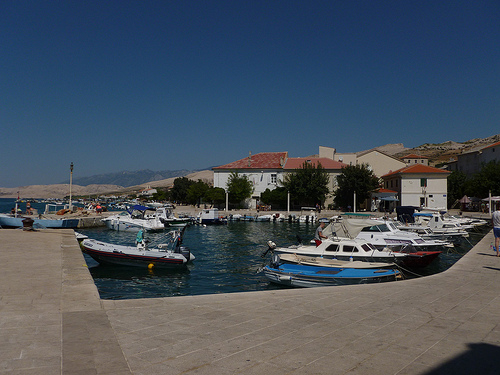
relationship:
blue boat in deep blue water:
[261, 261, 402, 288] [76, 223, 314, 300]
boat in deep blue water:
[273, 234, 413, 266] [76, 223, 314, 300]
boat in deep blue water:
[310, 218, 455, 251] [76, 223, 314, 300]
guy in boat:
[313, 221, 327, 248] [306, 213, 458, 257]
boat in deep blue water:
[306, 213, 458, 257] [76, 223, 314, 300]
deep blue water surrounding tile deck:
[76, 223, 314, 300] [6, 221, 500, 374]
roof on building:
[209, 147, 283, 173] [205, 147, 286, 205]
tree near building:
[284, 159, 329, 207] [209, 148, 346, 211]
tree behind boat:
[284, 159, 329, 207] [260, 207, 325, 227]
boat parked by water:
[273, 235, 441, 267] [177, 220, 270, 285]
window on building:
[419, 177, 428, 188] [377, 158, 459, 209]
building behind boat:
[377, 158, 459, 209] [397, 204, 486, 231]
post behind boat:
[65, 160, 83, 210] [41, 205, 101, 230]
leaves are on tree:
[345, 173, 372, 190] [332, 162, 379, 215]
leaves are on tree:
[294, 175, 320, 189] [260, 158, 329, 206]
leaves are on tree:
[233, 184, 245, 197] [226, 172, 256, 206]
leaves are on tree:
[186, 185, 209, 203] [166, 175, 224, 206]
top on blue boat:
[266, 256, 399, 280] [261, 261, 402, 288]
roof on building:
[207, 148, 348, 174] [209, 149, 347, 205]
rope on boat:
[390, 256, 427, 280] [265, 233, 422, 270]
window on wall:
[270, 173, 281, 185] [244, 165, 286, 191]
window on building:
[419, 174, 429, 187] [380, 159, 455, 211]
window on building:
[415, 195, 430, 208] [380, 159, 455, 211]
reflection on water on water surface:
[243, 205, 309, 242] [73, 221, 497, 300]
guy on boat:
[313, 221, 327, 248] [303, 209, 455, 259]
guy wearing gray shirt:
[313, 221, 327, 248] [311, 223, 332, 243]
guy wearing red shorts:
[310, 220, 328, 247] [310, 235, 330, 246]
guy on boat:
[310, 220, 328, 247] [257, 212, 412, 273]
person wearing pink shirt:
[92, 199, 103, 217] [92, 200, 108, 213]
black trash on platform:
[14, 207, 41, 240] [2, 225, 139, 373]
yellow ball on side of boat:
[138, 254, 160, 275] [70, 221, 194, 272]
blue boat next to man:
[264, 249, 410, 292] [311, 219, 325, 247]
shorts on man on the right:
[490, 225, 499, 237] [491, 207, 500, 261]